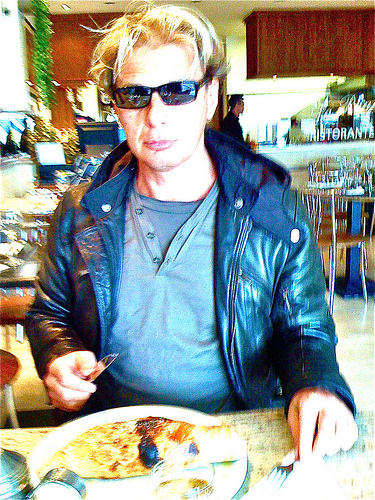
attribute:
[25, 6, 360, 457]
man — eating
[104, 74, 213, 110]
glasses — black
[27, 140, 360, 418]
jacket — dark, leather, wrinkled, black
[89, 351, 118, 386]
knife — silver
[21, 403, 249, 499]
plate — white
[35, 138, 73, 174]
monitor — behind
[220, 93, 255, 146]
worker — behind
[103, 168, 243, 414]
shirt — grey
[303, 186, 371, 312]
chair — silver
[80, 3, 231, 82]
hair — blond